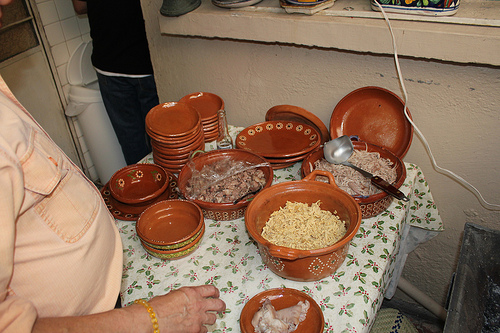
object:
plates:
[145, 101, 202, 138]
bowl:
[242, 168, 362, 283]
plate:
[234, 116, 321, 161]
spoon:
[322, 135, 411, 203]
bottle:
[216, 108, 235, 150]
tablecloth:
[110, 123, 446, 331]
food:
[259, 196, 349, 249]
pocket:
[9, 126, 104, 243]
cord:
[372, 1, 500, 208]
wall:
[142, 1, 499, 328]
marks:
[392, 76, 441, 86]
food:
[309, 150, 406, 194]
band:
[135, 297, 162, 332]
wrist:
[117, 296, 161, 333]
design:
[275, 122, 284, 130]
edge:
[283, 120, 299, 124]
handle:
[370, 175, 411, 203]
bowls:
[135, 197, 207, 250]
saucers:
[178, 91, 225, 121]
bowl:
[106, 163, 170, 208]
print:
[127, 169, 144, 180]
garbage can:
[63, 39, 131, 188]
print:
[98, 121, 447, 333]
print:
[265, 123, 273, 131]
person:
[1, 71, 228, 332]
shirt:
[0, 76, 127, 331]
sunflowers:
[149, 170, 162, 182]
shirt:
[85, 1, 156, 75]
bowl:
[301, 137, 408, 222]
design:
[306, 257, 326, 277]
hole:
[47, 155, 59, 167]